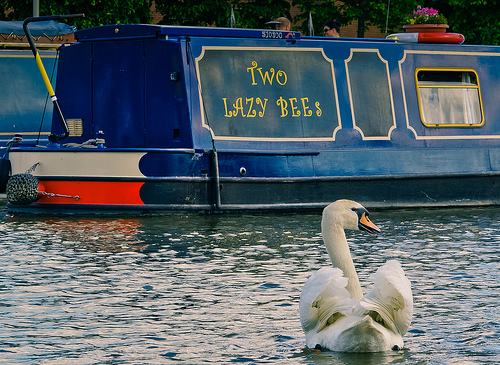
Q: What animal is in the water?
A: White swan.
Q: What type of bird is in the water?
A: Swan.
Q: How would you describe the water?
A: Calm.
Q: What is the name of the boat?
A: Two Lazy Bees.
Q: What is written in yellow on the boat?
A: Two Lazy Bees.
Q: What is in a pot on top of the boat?
A: Pink flowers.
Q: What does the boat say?
A: "Two Lazy Bees.".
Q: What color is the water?
A: Bluish.